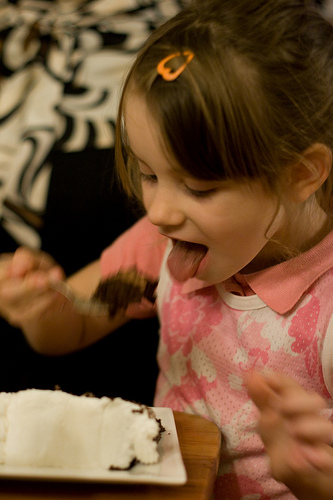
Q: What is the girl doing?
A: Eating cake.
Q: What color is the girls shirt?
A: Pink and white.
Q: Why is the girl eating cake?
A: It is her birthday.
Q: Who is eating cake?
A: A girl.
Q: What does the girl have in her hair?
A: A beret.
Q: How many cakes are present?
A: One.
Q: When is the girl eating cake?
A: Now.